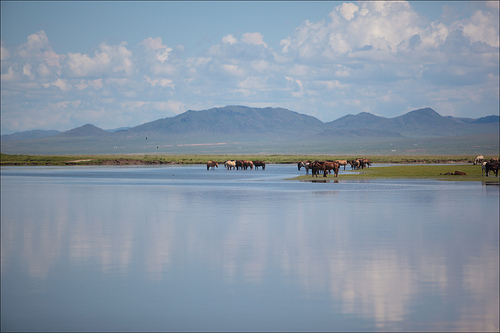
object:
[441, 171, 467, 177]
clump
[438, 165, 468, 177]
wood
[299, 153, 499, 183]
grass field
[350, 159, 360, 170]
horse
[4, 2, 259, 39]
blue sky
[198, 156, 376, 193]
horses water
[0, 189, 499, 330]
river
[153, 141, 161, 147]
birds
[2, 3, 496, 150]
air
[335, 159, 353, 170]
horse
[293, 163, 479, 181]
grass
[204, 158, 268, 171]
animals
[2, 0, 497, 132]
clouds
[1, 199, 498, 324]
reflection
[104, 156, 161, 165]
shoreline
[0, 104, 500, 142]
mountain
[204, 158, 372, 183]
horse group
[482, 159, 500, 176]
horse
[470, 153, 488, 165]
white horse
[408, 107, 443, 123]
mountain peak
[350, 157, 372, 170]
wild animal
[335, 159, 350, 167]
wild animal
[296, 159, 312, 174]
wild animal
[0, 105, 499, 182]
land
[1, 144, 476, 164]
forest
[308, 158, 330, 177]
horse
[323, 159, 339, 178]
horse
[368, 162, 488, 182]
ground